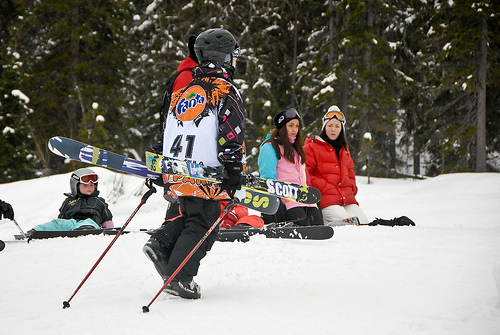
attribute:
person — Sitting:
[258, 109, 321, 224]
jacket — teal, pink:
[261, 139, 313, 213]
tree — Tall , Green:
[446, 1, 499, 171]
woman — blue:
[260, 105, 315, 225]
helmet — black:
[183, 24, 268, 86]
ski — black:
[211, 217, 338, 249]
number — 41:
[167, 121, 207, 165]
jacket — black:
[124, 81, 311, 221]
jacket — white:
[131, 77, 266, 182]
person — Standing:
[144, 29, 243, 301]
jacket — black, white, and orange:
[150, 68, 251, 209]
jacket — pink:
[252, 147, 303, 178]